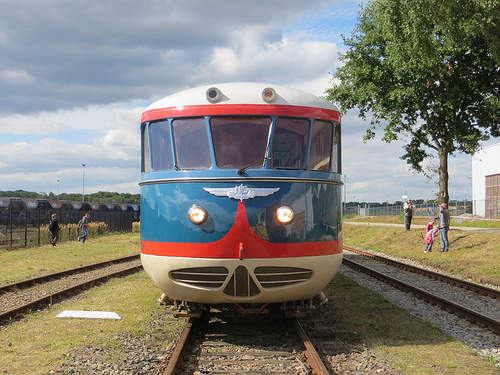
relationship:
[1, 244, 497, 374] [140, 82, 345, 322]
tracks are for train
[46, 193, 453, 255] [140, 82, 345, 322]
people near train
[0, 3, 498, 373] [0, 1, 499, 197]
day with clouds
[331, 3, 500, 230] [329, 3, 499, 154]
tree with leaves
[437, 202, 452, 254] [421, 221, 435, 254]
mom with daughter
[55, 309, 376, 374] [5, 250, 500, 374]
rocks with grass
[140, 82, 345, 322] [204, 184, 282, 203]
train has logo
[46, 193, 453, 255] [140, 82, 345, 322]
people watch train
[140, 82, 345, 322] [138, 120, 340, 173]
train has windows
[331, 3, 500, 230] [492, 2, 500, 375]
tree on side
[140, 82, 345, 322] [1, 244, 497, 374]
train has tracks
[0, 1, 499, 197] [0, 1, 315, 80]
clouds in sky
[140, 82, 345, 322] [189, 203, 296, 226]
train has lights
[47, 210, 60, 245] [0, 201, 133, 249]
boy on fence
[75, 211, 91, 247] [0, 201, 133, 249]
boy on fence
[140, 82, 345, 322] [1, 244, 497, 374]
train on tracks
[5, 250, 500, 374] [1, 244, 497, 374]
grass near tracks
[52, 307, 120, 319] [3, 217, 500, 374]
wood on ground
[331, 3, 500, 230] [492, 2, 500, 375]
tree on right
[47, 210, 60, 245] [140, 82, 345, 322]
boy left of train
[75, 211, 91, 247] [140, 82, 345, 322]
boy left of train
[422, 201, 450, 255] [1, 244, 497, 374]
mom and daughter near tracks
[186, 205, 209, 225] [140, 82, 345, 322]
headlight on train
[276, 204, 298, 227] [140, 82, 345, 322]
right headlight on train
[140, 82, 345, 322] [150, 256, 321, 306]
train has design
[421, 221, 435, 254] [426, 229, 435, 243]
daughter in jacket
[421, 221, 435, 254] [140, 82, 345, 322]
daughter right of train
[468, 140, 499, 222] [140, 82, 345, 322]
building right of train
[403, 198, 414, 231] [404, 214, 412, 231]
man in pants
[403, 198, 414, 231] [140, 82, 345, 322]
man right of train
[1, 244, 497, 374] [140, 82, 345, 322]
tracks in front of train